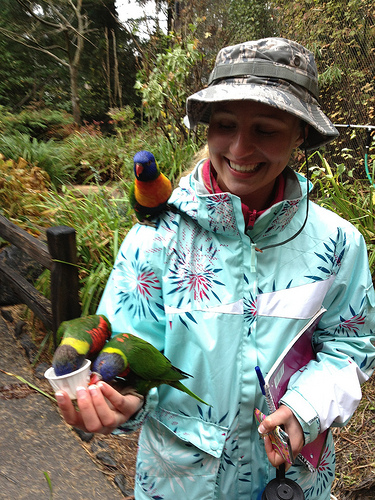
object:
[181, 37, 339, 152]
hat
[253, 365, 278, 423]
pen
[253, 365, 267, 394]
cap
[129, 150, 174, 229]
parrot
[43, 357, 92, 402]
paper ramikin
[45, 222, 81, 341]
fence post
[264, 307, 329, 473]
note book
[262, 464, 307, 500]
cover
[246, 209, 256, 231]
zipper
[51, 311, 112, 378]
parrot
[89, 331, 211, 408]
parrot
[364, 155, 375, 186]
hose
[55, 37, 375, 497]
woman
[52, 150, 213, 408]
three birds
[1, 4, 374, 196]
woods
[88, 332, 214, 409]
parrots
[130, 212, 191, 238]
shoulder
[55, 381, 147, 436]
hand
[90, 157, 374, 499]
jacket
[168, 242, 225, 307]
print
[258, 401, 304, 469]
hand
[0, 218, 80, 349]
fence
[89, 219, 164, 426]
arm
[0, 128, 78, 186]
grass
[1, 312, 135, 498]
street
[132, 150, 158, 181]
head